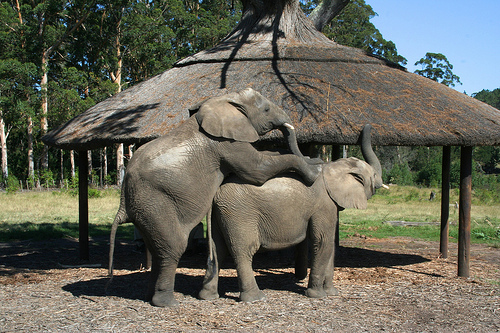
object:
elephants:
[108, 88, 389, 306]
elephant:
[106, 88, 323, 307]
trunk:
[357, 125, 382, 179]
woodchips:
[0, 243, 500, 333]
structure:
[41, 0, 500, 277]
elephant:
[198, 122, 389, 302]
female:
[200, 123, 391, 303]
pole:
[457, 144, 472, 277]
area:
[2, 0, 488, 187]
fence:
[1, 178, 500, 193]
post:
[457, 144, 471, 278]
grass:
[3, 189, 500, 245]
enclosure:
[0, 180, 500, 331]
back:
[220, 176, 306, 212]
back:
[127, 116, 208, 170]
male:
[109, 88, 321, 306]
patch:
[248, 177, 292, 195]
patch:
[145, 130, 212, 170]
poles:
[76, 150, 87, 264]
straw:
[44, 0, 500, 147]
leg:
[223, 142, 322, 186]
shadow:
[0, 222, 441, 309]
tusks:
[283, 123, 294, 130]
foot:
[239, 290, 263, 301]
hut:
[43, 0, 500, 277]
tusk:
[284, 122, 294, 129]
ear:
[194, 98, 258, 143]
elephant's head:
[324, 156, 383, 205]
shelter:
[41, 0, 500, 278]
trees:
[0, 0, 466, 189]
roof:
[41, 0, 500, 149]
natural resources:
[380, 82, 442, 120]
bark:
[0, 254, 500, 333]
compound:
[0, 184, 500, 333]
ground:
[0, 180, 499, 333]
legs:
[140, 233, 188, 294]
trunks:
[0, 51, 124, 187]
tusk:
[382, 184, 389, 189]